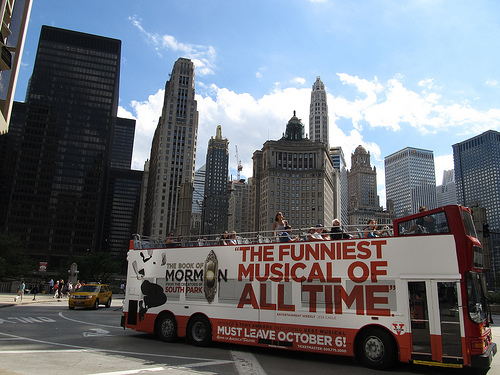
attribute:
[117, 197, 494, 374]
bus — white, doubledecker, red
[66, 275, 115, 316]
cab — yellow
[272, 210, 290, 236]
passenger — standing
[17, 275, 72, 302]
people — walking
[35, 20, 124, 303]
building — black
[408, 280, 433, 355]
door — glass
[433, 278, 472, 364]
door — glass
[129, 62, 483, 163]
clouds — white, fluffy, large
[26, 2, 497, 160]
sky — blue, clear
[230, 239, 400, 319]
words — red, large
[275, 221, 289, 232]
shirt — short sleeve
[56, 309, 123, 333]
lines — white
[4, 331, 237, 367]
lines — white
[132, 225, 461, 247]
floor — opened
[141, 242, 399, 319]
advertisement — book of mormon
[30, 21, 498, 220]
buildings — tall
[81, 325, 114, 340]
arrow — white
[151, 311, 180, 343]
wheel — black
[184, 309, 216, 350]
wheel — black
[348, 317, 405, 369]
wheel — black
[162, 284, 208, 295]
words — red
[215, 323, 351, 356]
words — white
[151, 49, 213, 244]
building — gray, tall